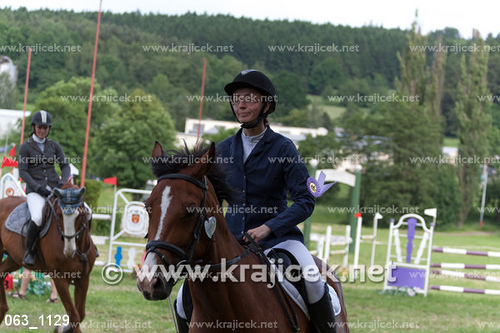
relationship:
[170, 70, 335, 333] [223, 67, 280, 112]
rider wearing helmet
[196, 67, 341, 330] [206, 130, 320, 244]
rider wearing jacket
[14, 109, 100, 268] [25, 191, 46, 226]
woman wearing pants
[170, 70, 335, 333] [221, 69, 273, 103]
rider wearing helmet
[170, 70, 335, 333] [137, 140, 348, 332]
rider riding horse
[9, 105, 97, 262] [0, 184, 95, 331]
woman riding horse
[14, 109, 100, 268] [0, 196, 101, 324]
woman steering horse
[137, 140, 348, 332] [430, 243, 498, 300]
horse jumping poles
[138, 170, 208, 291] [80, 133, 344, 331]
face on horse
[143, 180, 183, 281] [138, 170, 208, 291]
markings on face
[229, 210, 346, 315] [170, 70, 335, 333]
pants on a rider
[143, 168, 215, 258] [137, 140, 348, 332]
something on a horse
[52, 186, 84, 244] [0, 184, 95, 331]
something on a horse